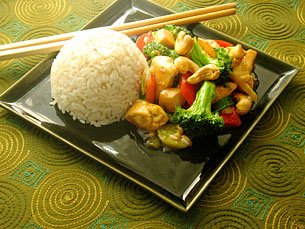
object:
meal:
[50, 24, 259, 152]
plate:
[0, 2, 299, 212]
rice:
[51, 27, 148, 128]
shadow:
[45, 107, 136, 153]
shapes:
[30, 169, 109, 228]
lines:
[233, 188, 273, 220]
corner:
[172, 194, 200, 215]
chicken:
[125, 100, 167, 132]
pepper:
[221, 111, 241, 128]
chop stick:
[0, 2, 237, 58]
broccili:
[174, 80, 222, 135]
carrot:
[145, 72, 157, 103]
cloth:
[0, 1, 304, 228]